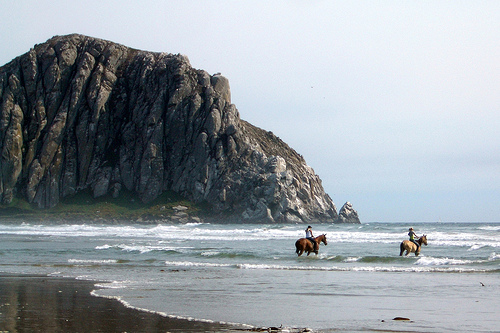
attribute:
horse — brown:
[399, 232, 428, 255]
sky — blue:
[264, 18, 499, 170]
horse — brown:
[295, 231, 327, 256]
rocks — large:
[341, 202, 356, 225]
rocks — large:
[168, 201, 202, 225]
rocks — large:
[0, 31, 362, 221]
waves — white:
[154, 226, 284, 241]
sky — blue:
[318, 49, 474, 124]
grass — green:
[13, 198, 205, 232]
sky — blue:
[291, 26, 471, 106]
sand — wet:
[3, 273, 285, 330]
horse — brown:
[290, 231, 325, 261]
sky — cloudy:
[380, 42, 437, 92]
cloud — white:
[354, 81, 434, 133]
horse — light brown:
[398, 234, 427, 256]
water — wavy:
[245, 260, 454, 308]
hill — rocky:
[1, 31, 354, 226]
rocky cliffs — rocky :
[0, 32, 361, 226]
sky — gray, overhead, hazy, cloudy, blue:
[0, 1, 498, 222]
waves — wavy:
[159, 230, 264, 275]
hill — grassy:
[22, 200, 202, 223]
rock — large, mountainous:
[1, 52, 366, 251]